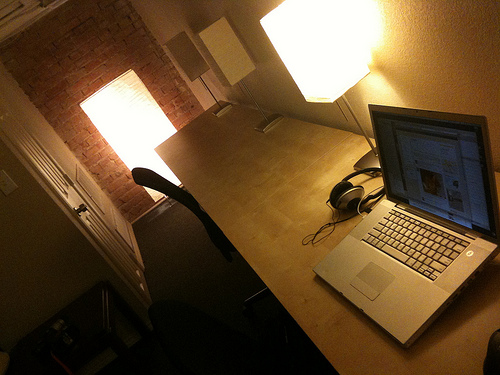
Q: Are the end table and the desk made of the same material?
A: Yes, both the end table and the desk are made of wood.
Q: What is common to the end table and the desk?
A: The material, both the end table and the desk are wooden.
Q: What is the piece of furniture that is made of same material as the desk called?
A: The piece of furniture is an end table.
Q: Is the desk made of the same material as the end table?
A: Yes, both the desk and the end table are made of wood.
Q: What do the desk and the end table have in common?
A: The material, both the desk and the end table are wooden.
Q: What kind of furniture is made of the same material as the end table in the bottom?
A: The desk is made of the same material as the end table.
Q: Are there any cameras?
A: No, there are no cameras.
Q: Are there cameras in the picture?
A: No, there are no cameras.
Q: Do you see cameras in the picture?
A: No, there are no cameras.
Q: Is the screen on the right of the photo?
A: Yes, the screen is on the right of the image.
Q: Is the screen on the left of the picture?
A: No, the screen is on the right of the image.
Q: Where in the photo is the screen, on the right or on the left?
A: The screen is on the right of the image.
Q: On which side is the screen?
A: The screen is on the right of the image.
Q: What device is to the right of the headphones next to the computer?
A: The device is a screen.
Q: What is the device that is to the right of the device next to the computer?
A: The device is a screen.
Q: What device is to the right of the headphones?
A: The device is a screen.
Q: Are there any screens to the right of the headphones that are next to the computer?
A: Yes, there is a screen to the right of the headphones.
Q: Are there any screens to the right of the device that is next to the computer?
A: Yes, there is a screen to the right of the headphones.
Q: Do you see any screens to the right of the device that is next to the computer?
A: Yes, there is a screen to the right of the headphones.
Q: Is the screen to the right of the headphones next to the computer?
A: Yes, the screen is to the right of the headphones.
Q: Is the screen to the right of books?
A: No, the screen is to the right of the headphones.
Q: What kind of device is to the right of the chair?
A: The device is a screen.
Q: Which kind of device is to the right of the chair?
A: The device is a screen.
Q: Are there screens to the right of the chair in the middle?
A: Yes, there is a screen to the right of the chair.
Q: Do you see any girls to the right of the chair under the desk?
A: No, there is a screen to the right of the chair.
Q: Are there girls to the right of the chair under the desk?
A: No, there is a screen to the right of the chair.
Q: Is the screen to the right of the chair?
A: Yes, the screen is to the right of the chair.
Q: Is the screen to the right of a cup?
A: No, the screen is to the right of the chair.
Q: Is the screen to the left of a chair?
A: No, the screen is to the right of a chair.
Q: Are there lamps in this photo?
A: Yes, there is a lamp.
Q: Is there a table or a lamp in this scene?
A: Yes, there is a lamp.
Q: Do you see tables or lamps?
A: Yes, there is a lamp.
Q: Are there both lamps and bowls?
A: No, there is a lamp but no bowls.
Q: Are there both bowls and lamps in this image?
A: No, there is a lamp but no bowls.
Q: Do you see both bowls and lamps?
A: No, there is a lamp but no bowls.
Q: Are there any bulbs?
A: No, there are no bulbs.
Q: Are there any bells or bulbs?
A: No, there are no bulbs or bells.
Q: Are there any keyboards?
A: Yes, there is a keyboard.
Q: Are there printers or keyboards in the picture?
A: Yes, there is a keyboard.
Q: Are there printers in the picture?
A: No, there are no printers.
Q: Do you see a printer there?
A: No, there are no printers.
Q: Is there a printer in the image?
A: No, there are no printers.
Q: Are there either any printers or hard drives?
A: No, there are no printers or hard drives.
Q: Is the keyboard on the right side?
A: Yes, the keyboard is on the right of the image.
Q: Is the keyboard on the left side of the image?
A: No, the keyboard is on the right of the image.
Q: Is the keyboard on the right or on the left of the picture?
A: The keyboard is on the right of the image.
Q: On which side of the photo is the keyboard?
A: The keyboard is on the right of the image.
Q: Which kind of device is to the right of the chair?
A: The device is a keyboard.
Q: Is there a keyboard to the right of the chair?
A: Yes, there is a keyboard to the right of the chair.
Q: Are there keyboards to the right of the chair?
A: Yes, there is a keyboard to the right of the chair.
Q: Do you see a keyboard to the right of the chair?
A: Yes, there is a keyboard to the right of the chair.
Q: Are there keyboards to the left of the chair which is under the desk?
A: No, the keyboard is to the right of the chair.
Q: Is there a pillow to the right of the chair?
A: No, there is a keyboard to the right of the chair.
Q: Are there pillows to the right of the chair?
A: No, there is a keyboard to the right of the chair.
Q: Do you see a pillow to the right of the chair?
A: No, there is a keyboard to the right of the chair.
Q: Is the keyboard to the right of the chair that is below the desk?
A: Yes, the keyboard is to the right of the chair.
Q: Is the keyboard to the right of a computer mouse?
A: No, the keyboard is to the right of the chair.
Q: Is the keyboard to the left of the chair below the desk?
A: No, the keyboard is to the right of the chair.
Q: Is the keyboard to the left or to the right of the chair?
A: The keyboard is to the right of the chair.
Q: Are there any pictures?
A: No, there are no pictures.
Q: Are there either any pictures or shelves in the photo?
A: No, there are no pictures or shelves.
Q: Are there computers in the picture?
A: Yes, there is a computer.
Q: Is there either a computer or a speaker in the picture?
A: Yes, there is a computer.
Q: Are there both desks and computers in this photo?
A: Yes, there are both a computer and a desk.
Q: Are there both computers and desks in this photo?
A: Yes, there are both a computer and a desk.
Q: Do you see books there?
A: No, there are no books.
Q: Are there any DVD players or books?
A: No, there are no books or DVD players.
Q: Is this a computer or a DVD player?
A: This is a computer.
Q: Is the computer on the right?
A: Yes, the computer is on the right of the image.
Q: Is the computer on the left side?
A: No, the computer is on the right of the image.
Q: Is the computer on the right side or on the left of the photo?
A: The computer is on the right of the image.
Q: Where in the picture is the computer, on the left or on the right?
A: The computer is on the right of the image.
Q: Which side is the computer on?
A: The computer is on the right of the image.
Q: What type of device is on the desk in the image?
A: The device is a computer.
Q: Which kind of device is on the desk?
A: The device is a computer.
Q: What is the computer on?
A: The computer is on the desk.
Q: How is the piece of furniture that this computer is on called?
A: The piece of furniture is a desk.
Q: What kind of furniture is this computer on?
A: The computer is on the desk.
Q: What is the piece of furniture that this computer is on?
A: The piece of furniture is a desk.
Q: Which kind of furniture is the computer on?
A: The computer is on the desk.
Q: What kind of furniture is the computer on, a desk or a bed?
A: The computer is on a desk.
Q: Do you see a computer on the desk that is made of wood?
A: Yes, there is a computer on the desk.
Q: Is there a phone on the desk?
A: No, there is a computer on the desk.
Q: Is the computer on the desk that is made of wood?
A: Yes, the computer is on the desk.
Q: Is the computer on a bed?
A: No, the computer is on the desk.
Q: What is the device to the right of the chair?
A: The device is a computer.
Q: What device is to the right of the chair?
A: The device is a computer.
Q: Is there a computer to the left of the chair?
A: No, the computer is to the right of the chair.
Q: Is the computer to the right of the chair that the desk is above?
A: Yes, the computer is to the right of the chair.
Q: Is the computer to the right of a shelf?
A: No, the computer is to the right of the chair.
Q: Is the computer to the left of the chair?
A: No, the computer is to the right of the chair.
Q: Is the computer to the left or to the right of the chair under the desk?
A: The computer is to the right of the chair.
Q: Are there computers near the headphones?
A: Yes, there is a computer near the headphones.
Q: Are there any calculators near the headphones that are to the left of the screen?
A: No, there is a computer near the headphones.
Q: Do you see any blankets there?
A: No, there are no blankets.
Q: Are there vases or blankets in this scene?
A: No, there are no blankets or vases.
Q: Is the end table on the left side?
A: Yes, the end table is on the left of the image.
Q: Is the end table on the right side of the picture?
A: No, the end table is on the left of the image.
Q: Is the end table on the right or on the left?
A: The end table is on the left of the image.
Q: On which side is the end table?
A: The end table is on the left of the image.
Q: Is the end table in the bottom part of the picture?
A: Yes, the end table is in the bottom of the image.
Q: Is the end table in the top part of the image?
A: No, the end table is in the bottom of the image.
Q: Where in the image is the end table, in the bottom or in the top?
A: The end table is in the bottom of the image.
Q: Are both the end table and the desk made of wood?
A: Yes, both the end table and the desk are made of wood.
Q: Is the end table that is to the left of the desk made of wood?
A: Yes, the end table is made of wood.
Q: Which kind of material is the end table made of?
A: The end table is made of wood.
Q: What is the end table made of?
A: The end table is made of wood.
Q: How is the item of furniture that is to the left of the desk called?
A: The piece of furniture is an end table.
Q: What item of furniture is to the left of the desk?
A: The piece of furniture is an end table.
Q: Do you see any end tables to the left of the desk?
A: Yes, there is an end table to the left of the desk.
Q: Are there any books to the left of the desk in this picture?
A: No, there is an end table to the left of the desk.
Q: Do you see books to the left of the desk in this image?
A: No, there is an end table to the left of the desk.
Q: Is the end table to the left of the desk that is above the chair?
A: Yes, the end table is to the left of the desk.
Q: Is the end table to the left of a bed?
A: No, the end table is to the left of the desk.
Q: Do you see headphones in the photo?
A: Yes, there are headphones.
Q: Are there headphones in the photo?
A: Yes, there are headphones.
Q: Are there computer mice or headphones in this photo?
A: Yes, there are headphones.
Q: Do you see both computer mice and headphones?
A: No, there are headphones but no computer mice.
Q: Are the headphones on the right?
A: Yes, the headphones are on the right of the image.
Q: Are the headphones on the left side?
A: No, the headphones are on the right of the image.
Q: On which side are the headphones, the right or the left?
A: The headphones are on the right of the image.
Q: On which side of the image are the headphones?
A: The headphones are on the right of the image.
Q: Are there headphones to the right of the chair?
A: Yes, there are headphones to the right of the chair.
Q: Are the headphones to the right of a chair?
A: Yes, the headphones are to the right of a chair.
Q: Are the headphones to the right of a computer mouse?
A: No, the headphones are to the right of a chair.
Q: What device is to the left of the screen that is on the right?
A: The device is headphones.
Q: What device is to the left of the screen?
A: The device is headphones.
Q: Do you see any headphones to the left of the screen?
A: Yes, there are headphones to the left of the screen.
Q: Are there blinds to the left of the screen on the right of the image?
A: No, there are headphones to the left of the screen.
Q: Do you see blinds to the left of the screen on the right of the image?
A: No, there are headphones to the left of the screen.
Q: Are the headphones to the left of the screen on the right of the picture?
A: Yes, the headphones are to the left of the screen.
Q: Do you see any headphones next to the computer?
A: Yes, there are headphones next to the computer.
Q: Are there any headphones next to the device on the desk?
A: Yes, there are headphones next to the computer.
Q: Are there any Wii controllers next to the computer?
A: No, there are headphones next to the computer.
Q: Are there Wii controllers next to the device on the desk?
A: No, there are headphones next to the computer.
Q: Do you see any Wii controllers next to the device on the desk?
A: No, there are headphones next to the computer.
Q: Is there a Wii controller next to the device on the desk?
A: No, there are headphones next to the computer.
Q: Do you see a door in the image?
A: Yes, there is a door.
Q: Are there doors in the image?
A: Yes, there is a door.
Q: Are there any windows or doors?
A: Yes, there is a door.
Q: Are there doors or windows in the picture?
A: Yes, there is a door.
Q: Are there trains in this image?
A: No, there are no trains.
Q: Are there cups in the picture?
A: No, there are no cups.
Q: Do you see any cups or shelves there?
A: No, there are no cups or shelves.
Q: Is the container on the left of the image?
A: Yes, the container is on the left of the image.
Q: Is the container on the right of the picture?
A: No, the container is on the left of the image.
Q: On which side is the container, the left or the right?
A: The container is on the left of the image.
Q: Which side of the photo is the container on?
A: The container is on the left of the image.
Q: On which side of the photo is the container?
A: The container is on the left of the image.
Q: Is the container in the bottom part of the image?
A: Yes, the container is in the bottom of the image.